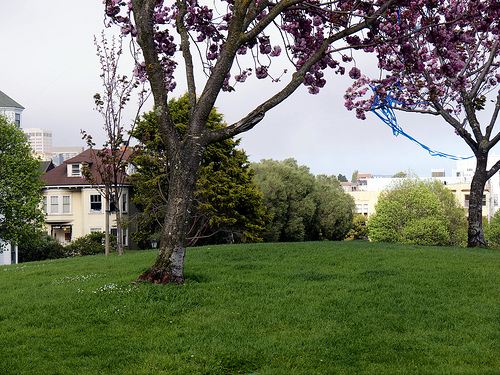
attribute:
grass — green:
[195, 248, 332, 359]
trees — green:
[234, 141, 343, 241]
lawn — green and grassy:
[226, 294, 307, 350]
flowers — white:
[65, 274, 151, 309]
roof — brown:
[39, 148, 138, 188]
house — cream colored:
[36, 186, 126, 253]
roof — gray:
[2, 90, 23, 110]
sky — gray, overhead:
[3, 8, 468, 168]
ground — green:
[8, 237, 480, 363]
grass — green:
[209, 279, 314, 339]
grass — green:
[329, 304, 407, 361]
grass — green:
[280, 288, 367, 348]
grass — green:
[277, 307, 369, 366]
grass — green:
[276, 291, 408, 361]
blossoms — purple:
[100, 7, 387, 96]